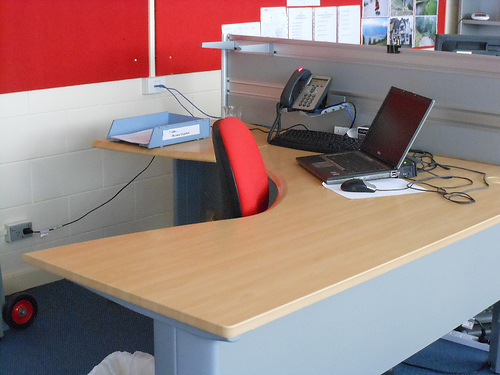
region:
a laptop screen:
[366, 101, 415, 153]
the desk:
[174, 237, 288, 295]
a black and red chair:
[215, 123, 270, 205]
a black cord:
[427, 176, 469, 203]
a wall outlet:
[5, 222, 32, 240]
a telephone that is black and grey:
[284, 62, 323, 110]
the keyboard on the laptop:
[334, 148, 367, 173]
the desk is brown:
[233, 224, 305, 279]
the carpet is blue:
[41, 315, 87, 352]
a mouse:
[344, 176, 374, 193]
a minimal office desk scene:
[5, 5, 490, 363]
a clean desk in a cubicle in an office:
[0, 0, 490, 370]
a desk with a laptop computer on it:
[30, 53, 496, 370]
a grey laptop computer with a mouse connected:
[281, 87, 449, 197]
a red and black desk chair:
[196, 113, 279, 218]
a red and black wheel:
[3, 293, 37, 324]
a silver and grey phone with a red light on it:
[275, 58, 334, 120]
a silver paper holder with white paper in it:
[108, 108, 210, 152]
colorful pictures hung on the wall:
[356, 0, 450, 47]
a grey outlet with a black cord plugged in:
[0, 155, 156, 242]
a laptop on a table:
[279, 78, 479, 250]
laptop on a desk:
[279, 105, 424, 187]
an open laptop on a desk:
[273, 86, 444, 182]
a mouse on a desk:
[304, 155, 456, 264]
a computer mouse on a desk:
[343, 170, 448, 232]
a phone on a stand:
[271, 58, 333, 108]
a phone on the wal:
[255, 34, 394, 184]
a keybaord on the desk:
[291, 111, 406, 211]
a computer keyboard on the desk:
[260, 101, 404, 203]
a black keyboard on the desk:
[269, 103, 404, 178]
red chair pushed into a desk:
[205, 103, 279, 224]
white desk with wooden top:
[16, 78, 498, 374]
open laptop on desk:
[294, 87, 451, 188]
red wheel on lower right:
[2, 292, 42, 336]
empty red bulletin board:
[3, 0, 149, 106]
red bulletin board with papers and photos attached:
[154, 0, 439, 71]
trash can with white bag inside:
[80, 350, 157, 373]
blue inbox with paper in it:
[105, 109, 216, 154]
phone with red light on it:
[262, 67, 337, 141]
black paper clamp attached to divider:
[382, 31, 405, 58]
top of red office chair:
[211, 114, 269, 216]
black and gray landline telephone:
[266, 68, 333, 140]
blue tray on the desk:
[105, 110, 210, 146]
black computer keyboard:
[268, 127, 361, 152]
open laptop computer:
[295, 86, 435, 184]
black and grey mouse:
[339, 177, 376, 193]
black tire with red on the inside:
[1, 290, 39, 329]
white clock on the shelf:
[471, 11, 489, 20]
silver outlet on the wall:
[5, 218, 34, 242]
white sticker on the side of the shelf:
[161, 123, 201, 139]